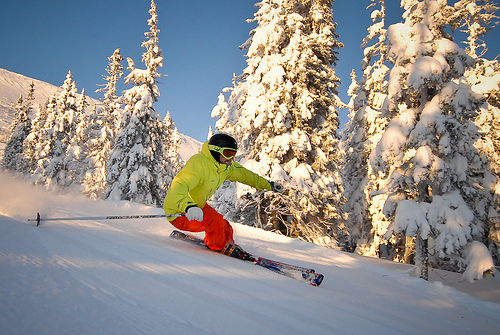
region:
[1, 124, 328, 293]
Man is downhill skiing at fast rate of speed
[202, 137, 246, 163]
Skier's goggles are framed in neon yellow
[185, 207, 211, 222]
Skier is wearing solid white gloves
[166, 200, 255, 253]
Skier's pants are bright orange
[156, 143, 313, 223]
Skier's jacket is neon yellow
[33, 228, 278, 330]
Hill is covered with bright white snow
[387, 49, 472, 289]
Tree branches are weighted down with ice and snow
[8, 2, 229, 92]
Sky is clear blue and bright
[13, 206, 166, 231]
Man's ski pole is white with black accents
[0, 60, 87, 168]
Steep section of snow covered hill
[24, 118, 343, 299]
skier skiing on snow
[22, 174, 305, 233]
skier with two poles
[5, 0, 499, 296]
trees are covered in snow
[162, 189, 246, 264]
skier wearing orange ski pants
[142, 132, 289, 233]
a skier wearing a yellow jacket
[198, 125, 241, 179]
skier wearing yellow and orange goggles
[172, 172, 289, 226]
a skier wearing white gloves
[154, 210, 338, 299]
a skier using two skis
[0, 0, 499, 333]
the snow is white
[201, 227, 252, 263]
skier wearing black boots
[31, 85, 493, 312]
a skier on a slope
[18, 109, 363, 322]
this skier is tackling the slopes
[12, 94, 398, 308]
the skier is using good form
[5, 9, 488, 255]
a clear day for skiing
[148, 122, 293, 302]
the skier is wearing red and yellow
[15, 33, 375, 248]
the pine trees are covered with snow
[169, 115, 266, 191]
this skier has on black and yellow goggles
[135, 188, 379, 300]
the skier is using good form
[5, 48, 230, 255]
a hill in the background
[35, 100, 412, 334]
a skier is in the shadows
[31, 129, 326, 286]
a skier going downhill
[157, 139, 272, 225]
a yellow winter jacket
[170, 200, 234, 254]
red winter pants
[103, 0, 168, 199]
a snow covered evergreen tree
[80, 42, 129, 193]
a snow covered evergreen tree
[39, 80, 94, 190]
a snow covered evergreen tree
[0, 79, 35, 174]
a snow covered evergreen tree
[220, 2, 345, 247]
a snow covered evergreen tree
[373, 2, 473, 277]
a snow covered evergreen tree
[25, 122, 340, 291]
A skier speeding down a hill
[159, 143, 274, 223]
Skier's bright yellow padded jacket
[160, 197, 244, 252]
Skier's bright red pants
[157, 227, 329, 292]
Red white and blue skis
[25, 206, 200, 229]
A ski pole held in the skier's right hand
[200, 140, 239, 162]
Skier's yellow goggles with red lenses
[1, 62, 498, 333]
A white snow-covered hill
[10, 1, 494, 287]
A forest of tall, snow-covered pine trees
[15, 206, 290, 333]
Tracks in the snow from skis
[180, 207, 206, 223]
Skier's white glove